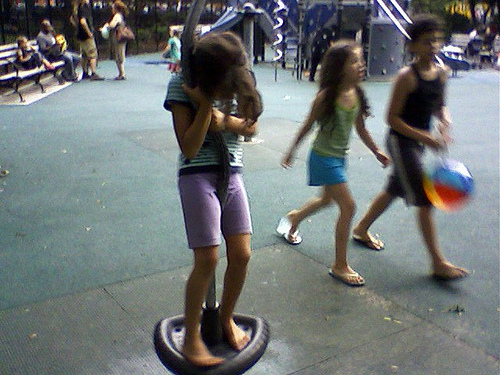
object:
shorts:
[175, 165, 253, 249]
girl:
[160, 26, 267, 374]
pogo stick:
[220, 137, 230, 200]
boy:
[350, 16, 474, 281]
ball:
[422, 152, 475, 213]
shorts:
[306, 147, 348, 184]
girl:
[282, 38, 389, 287]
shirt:
[310, 84, 367, 158]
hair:
[178, 31, 263, 126]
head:
[185, 33, 248, 97]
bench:
[0, 40, 70, 82]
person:
[35, 20, 82, 84]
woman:
[105, 0, 136, 81]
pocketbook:
[116, 24, 135, 42]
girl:
[13, 37, 55, 72]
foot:
[220, 312, 251, 351]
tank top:
[390, 58, 450, 138]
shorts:
[382, 129, 442, 207]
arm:
[171, 100, 213, 161]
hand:
[177, 83, 209, 102]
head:
[407, 20, 445, 62]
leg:
[394, 147, 472, 281]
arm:
[385, 71, 411, 142]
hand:
[426, 136, 442, 150]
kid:
[163, 25, 183, 72]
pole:
[204, 274, 217, 309]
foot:
[180, 332, 226, 365]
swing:
[157, 21, 261, 373]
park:
[5, 6, 499, 370]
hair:
[314, 40, 371, 125]